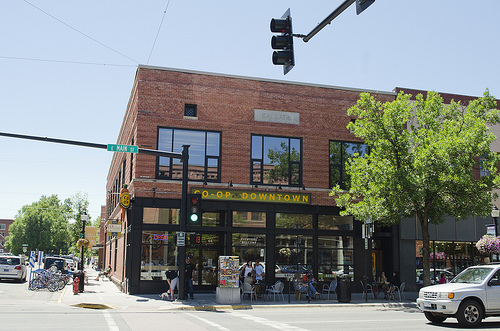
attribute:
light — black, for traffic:
[259, 9, 299, 79]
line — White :
[99, 307, 119, 329]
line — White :
[182, 309, 232, 330]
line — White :
[227, 304, 301, 329]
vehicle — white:
[412, 245, 498, 329]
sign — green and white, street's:
[105, 142, 140, 154]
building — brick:
[96, 62, 413, 310]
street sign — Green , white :
[103, 139, 137, 156]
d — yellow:
[239, 190, 248, 201]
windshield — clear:
[451, 267, 493, 284]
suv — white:
[416, 265, 498, 326]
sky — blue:
[0, 2, 500, 222]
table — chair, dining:
[237, 272, 280, 299]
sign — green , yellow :
[144, 173, 381, 260]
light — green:
[184, 190, 201, 232]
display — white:
[200, 228, 260, 315]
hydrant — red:
[52, 263, 114, 307]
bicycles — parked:
[26, 261, 81, 290]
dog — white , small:
[157, 287, 172, 302]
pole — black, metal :
[278, 0, 395, 50]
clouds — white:
[158, 21, 178, 44]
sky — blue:
[20, 18, 120, 80]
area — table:
[123, 239, 384, 328]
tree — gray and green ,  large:
[326, 88, 496, 318]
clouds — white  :
[10, 89, 147, 235]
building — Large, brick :
[86, 63, 497, 303]